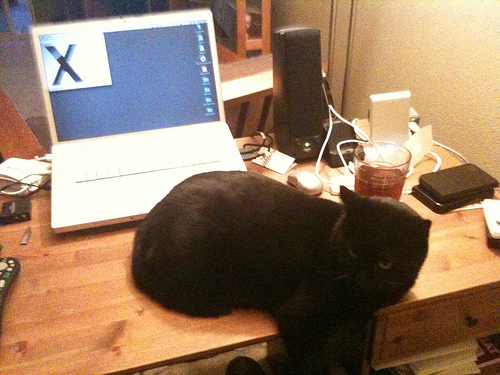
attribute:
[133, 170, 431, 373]
cat — black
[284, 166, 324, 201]
mouse — white, computer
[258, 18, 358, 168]
speaker — black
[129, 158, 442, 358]
cat desk — black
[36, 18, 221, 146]
screen — black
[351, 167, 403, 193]
liquid — brown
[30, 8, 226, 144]
screen — on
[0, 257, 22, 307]
remote control — black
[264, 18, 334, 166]
speaker — black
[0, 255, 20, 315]
remote — control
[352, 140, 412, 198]
glass — tea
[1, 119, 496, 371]
counter top — brown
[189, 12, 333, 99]
shelf — wooden, book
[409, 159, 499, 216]
cell phone — black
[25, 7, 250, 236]
laptop — white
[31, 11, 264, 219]
laptop — white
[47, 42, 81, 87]
x — blue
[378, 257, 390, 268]
eye — green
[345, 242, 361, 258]
eye — green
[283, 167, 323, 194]
mouse — white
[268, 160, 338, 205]
mouse — white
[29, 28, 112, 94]
x — blue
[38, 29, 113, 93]
patch — white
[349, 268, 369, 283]
nose — black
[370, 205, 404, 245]
hair — black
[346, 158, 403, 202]
liquid — brown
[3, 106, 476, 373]
desk — wooden, light colored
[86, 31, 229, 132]
background — blue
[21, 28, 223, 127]
background — white